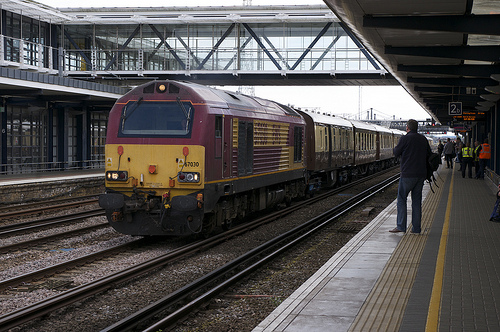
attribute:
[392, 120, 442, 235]
man — standing, waiting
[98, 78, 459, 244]
train — facing, yellow, red, not a passenger train, still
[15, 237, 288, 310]
gravel — brown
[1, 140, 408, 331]
tracks — wet, multiples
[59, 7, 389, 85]
walkway — empty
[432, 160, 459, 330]
line — yellow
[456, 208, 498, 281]
pattern — square, gray, brick, grey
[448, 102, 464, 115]
2b — black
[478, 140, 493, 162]
jacket — orange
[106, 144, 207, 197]
panel — yellow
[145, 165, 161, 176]
object — red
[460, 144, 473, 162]
jacket — yellow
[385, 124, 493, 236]
people — waiting, standing